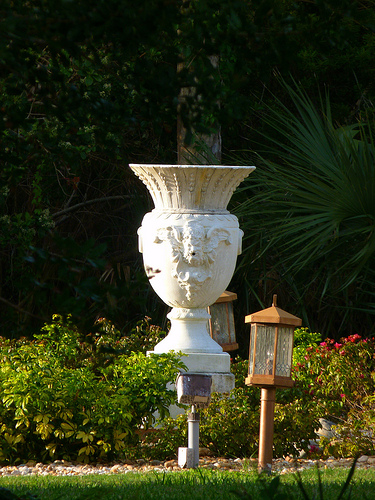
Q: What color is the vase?
A: White.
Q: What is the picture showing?
A: A garden landscape.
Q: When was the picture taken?
A: During the day.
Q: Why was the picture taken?
A: To capture the vase.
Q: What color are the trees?
A: Green.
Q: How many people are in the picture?
A: None.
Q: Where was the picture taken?
A: In a park.